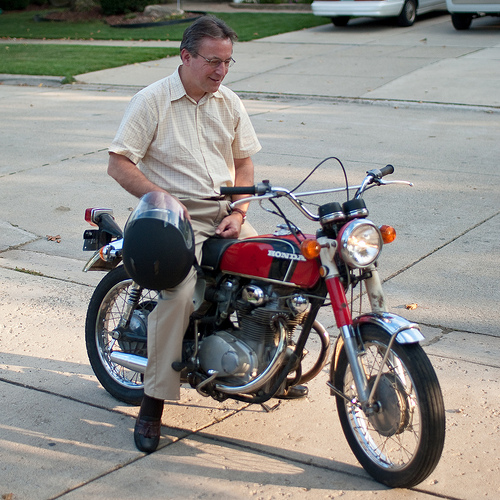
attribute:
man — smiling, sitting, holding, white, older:
[113, 15, 274, 410]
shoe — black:
[112, 388, 170, 458]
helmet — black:
[83, 166, 208, 308]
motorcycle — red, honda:
[82, 163, 442, 475]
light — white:
[328, 211, 387, 277]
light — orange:
[299, 227, 328, 279]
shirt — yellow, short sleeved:
[83, 43, 265, 225]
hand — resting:
[209, 187, 264, 263]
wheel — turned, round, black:
[286, 300, 473, 497]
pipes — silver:
[317, 286, 384, 419]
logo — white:
[253, 230, 315, 283]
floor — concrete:
[1, 264, 496, 499]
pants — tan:
[133, 174, 262, 409]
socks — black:
[125, 381, 177, 431]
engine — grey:
[163, 260, 314, 407]